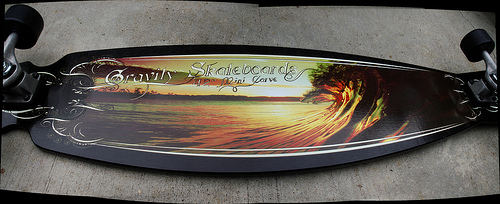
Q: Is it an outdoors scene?
A: Yes, it is outdoors.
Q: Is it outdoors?
A: Yes, it is outdoors.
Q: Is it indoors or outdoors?
A: It is outdoors.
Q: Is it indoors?
A: No, it is outdoors.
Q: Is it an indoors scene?
A: No, it is outdoors.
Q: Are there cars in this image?
A: No, there are no cars.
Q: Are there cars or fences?
A: No, there are no cars or fences.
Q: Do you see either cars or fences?
A: No, there are no cars or fences.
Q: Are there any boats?
A: No, there are no boats.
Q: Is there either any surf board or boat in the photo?
A: No, there are no boats or surfboards.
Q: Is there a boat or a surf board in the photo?
A: No, there are no boats or surfboards.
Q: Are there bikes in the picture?
A: No, there are no bikes.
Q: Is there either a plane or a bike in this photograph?
A: No, there are no bikes or airplanes.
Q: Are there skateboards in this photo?
A: Yes, there is a skateboard.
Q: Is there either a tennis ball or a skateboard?
A: Yes, there is a skateboard.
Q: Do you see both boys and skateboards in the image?
A: No, there is a skateboard but no boys.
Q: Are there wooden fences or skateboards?
A: Yes, there is a wood skateboard.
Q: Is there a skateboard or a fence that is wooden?
A: Yes, the skateboard is wooden.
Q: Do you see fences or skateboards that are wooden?
A: Yes, the skateboard is wooden.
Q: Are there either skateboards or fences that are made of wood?
A: Yes, the skateboard is made of wood.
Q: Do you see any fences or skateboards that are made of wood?
A: Yes, the skateboard is made of wood.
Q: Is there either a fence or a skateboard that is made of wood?
A: Yes, the skateboard is made of wood.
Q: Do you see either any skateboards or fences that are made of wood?
A: Yes, the skateboard is made of wood.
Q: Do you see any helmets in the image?
A: No, there are no helmets.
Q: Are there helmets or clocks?
A: No, there are no helmets or clocks.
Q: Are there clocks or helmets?
A: No, there are no helmets or clocks.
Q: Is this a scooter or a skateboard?
A: This is a skateboard.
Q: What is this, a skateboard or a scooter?
A: This is a skateboard.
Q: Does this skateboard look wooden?
A: Yes, the skateboard is wooden.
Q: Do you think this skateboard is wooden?
A: Yes, the skateboard is wooden.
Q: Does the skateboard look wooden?
A: Yes, the skateboard is wooden.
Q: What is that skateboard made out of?
A: The skateboard is made of wood.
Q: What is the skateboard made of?
A: The skateboard is made of wood.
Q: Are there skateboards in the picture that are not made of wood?
A: No, there is a skateboard but it is made of wood.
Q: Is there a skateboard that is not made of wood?
A: No, there is a skateboard but it is made of wood.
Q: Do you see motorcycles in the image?
A: No, there are no motorcycles.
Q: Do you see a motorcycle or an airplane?
A: No, there are no motorcycles or airplanes.